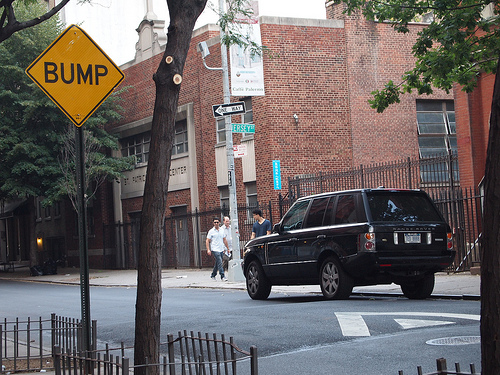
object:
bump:
[44, 61, 108, 85]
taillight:
[365, 241, 374, 249]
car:
[241, 187, 456, 300]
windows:
[416, 134, 446, 148]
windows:
[414, 99, 443, 112]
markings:
[394, 318, 457, 329]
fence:
[0, 320, 93, 374]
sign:
[231, 123, 256, 134]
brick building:
[3, 16, 452, 272]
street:
[0, 182, 483, 373]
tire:
[246, 259, 272, 300]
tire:
[319, 257, 355, 300]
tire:
[399, 272, 435, 300]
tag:
[404, 232, 422, 243]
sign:
[212, 101, 246, 118]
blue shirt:
[252, 219, 272, 238]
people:
[250, 209, 272, 239]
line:
[338, 314, 371, 337]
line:
[418, 312, 480, 321]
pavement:
[2, 276, 482, 373]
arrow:
[214, 104, 243, 116]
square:
[212, 101, 246, 118]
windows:
[416, 111, 445, 123]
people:
[206, 218, 231, 281]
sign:
[25, 24, 126, 127]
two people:
[204, 213, 232, 283]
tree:
[131, 0, 206, 375]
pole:
[73, 127, 90, 370]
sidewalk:
[65, 264, 485, 298]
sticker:
[388, 200, 398, 213]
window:
[366, 191, 442, 222]